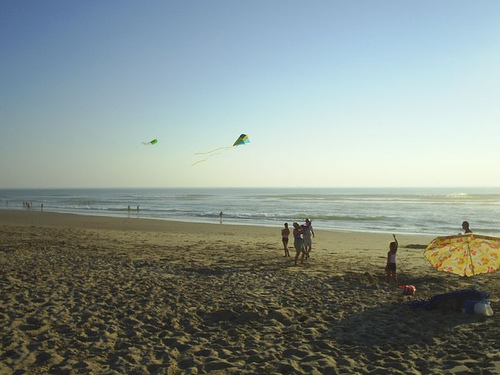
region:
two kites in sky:
[124, 125, 292, 169]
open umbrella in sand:
[420, 225, 498, 274]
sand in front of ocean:
[3, 205, 496, 323]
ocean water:
[8, 184, 497, 235]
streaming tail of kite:
[178, 145, 226, 169]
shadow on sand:
[312, 283, 449, 357]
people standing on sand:
[264, 210, 331, 275]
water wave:
[387, 189, 498, 208]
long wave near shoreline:
[202, 203, 399, 228]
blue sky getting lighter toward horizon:
[5, 5, 496, 186]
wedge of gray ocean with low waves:
[1, 185, 496, 235]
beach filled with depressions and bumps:
[1, 205, 493, 370]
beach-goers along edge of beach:
[1, 195, 226, 225]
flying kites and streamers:
[132, 125, 253, 170]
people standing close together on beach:
[275, 212, 317, 265]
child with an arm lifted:
[380, 225, 401, 287]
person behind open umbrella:
[425, 216, 498, 278]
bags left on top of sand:
[390, 272, 495, 322]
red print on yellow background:
[425, 231, 496, 277]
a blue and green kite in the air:
[190, 128, 257, 170]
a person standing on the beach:
[385, 230, 402, 284]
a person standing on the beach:
[277, 219, 292, 259]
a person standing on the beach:
[301, 217, 313, 259]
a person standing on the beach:
[289, 219, 308, 269]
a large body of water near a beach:
[3, 184, 498, 240]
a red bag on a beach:
[399, 282, 417, 298]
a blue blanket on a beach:
[407, 284, 494, 316]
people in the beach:
[0, 171, 423, 283]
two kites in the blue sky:
[136, 118, 306, 180]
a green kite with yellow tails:
[182, 128, 289, 173]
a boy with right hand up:
[379, 230, 408, 281]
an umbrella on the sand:
[416, 224, 498, 307]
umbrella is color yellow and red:
[420, 227, 498, 287]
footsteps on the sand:
[16, 252, 305, 364]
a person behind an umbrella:
[419, 213, 498, 286]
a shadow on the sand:
[311, 282, 471, 362]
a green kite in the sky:
[139, 131, 164, 149]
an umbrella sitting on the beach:
[422, 231, 499, 278]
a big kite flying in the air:
[228, 130, 248, 145]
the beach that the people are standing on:
[3, 215, 491, 373]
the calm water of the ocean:
[4, 188, 498, 240]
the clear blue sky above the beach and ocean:
[2, 5, 499, 194]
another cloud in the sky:
[138, 138, 163, 148]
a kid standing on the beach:
[381, 237, 401, 282]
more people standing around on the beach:
[6, 194, 145, 214]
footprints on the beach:
[68, 271, 243, 354]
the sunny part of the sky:
[371, 109, 499, 189]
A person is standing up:
[280, 221, 290, 256]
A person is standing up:
[290, 222, 308, 266]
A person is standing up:
[302, 217, 316, 257]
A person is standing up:
[385, 233, 399, 285]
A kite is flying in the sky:
[192, 130, 252, 167]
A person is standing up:
[460, 219, 472, 234]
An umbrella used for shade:
[426, 232, 499, 301]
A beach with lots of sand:
[0, 207, 499, 372]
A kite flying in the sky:
[134, 137, 158, 149]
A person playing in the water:
[218, 208, 223, 218]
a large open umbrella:
[431, 229, 498, 296]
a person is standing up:
[457, 221, 474, 238]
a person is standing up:
[374, 227, 402, 279]